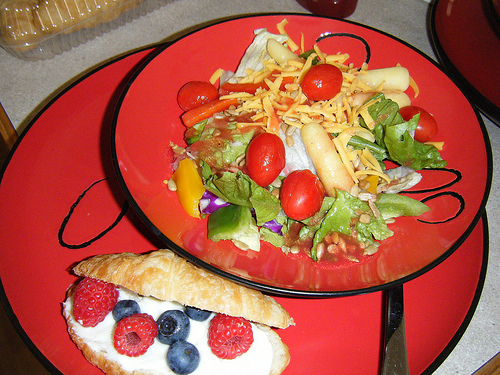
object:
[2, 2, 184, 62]
container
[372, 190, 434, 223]
pepper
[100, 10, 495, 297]
plate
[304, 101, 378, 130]
cheese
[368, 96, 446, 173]
lettuce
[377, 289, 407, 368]
handle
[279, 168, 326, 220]
grape tomato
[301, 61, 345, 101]
grape tomato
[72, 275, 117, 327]
raspberry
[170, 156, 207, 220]
yellow peppers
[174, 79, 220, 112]
red tomato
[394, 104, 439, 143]
red tomato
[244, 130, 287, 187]
red tomato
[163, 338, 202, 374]
blueberry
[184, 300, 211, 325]
blueberry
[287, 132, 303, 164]
salad dressing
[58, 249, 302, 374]
pastry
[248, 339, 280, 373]
cream cheese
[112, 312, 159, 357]
berries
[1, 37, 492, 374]
plate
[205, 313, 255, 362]
blueberries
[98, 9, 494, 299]
dish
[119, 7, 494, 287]
salad bowl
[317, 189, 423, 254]
lettuce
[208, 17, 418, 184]
shredded cheese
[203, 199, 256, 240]
green pepper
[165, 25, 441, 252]
salad